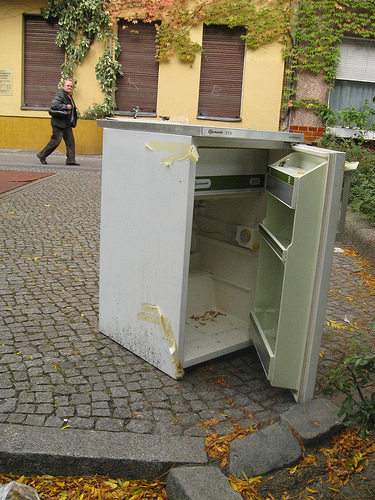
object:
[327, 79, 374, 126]
curtain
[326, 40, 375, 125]
window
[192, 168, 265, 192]
freezer part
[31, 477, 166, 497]
leaves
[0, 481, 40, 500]
plastic bag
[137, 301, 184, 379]
tape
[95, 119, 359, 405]
freezer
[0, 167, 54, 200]
outdoor carpet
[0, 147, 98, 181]
sidewalk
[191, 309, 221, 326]
bits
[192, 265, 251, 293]
shelf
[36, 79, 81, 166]
lady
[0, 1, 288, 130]
stucco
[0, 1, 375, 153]
building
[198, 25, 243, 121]
window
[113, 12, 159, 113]
window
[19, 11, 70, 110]
window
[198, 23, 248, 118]
shades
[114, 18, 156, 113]
shades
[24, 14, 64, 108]
shades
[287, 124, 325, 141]
red bricks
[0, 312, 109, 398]
brick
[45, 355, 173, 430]
stone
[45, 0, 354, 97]
plants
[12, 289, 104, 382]
pavers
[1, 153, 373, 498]
ground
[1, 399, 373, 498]
curb